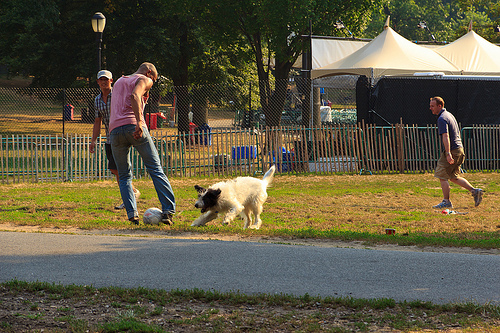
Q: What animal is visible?
A: A dog.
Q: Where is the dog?
A: In the grass.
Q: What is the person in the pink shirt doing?
A: Playing with a dog.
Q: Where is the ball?
A: On the ground.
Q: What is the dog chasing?
A: A ball.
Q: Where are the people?
A: At a park.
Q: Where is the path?
A: In front of the dog.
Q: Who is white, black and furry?
A: A dog.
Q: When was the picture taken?
A: During daytime.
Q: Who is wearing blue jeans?
A: Man in pink shirt.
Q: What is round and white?
A: A ball.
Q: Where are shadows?
A: On the ground.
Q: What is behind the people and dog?
A: A fence.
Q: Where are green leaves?
A: On trees.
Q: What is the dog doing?
A: Playing ball.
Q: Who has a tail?
A: The dog.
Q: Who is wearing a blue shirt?
A: Man on the right.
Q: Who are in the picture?
A: Three men.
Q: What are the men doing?
A: Playing soccer.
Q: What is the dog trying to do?
A: Get the ball.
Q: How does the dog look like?
A: Black and white.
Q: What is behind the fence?
A: A white tent.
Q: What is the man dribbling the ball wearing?
A: A pink shirt.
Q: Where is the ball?
A: Between the man in pink's legs.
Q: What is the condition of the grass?
A: Green and withering.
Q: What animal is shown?
A: A dog.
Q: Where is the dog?
A: Near the man.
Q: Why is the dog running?
A: It is trying to get the ball.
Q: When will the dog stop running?
A: After it gets the ball.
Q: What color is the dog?
A: White and black.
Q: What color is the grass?
A: Brown and green.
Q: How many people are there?
A: Three.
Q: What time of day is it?
A: Daytime.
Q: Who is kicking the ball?
A: A man.